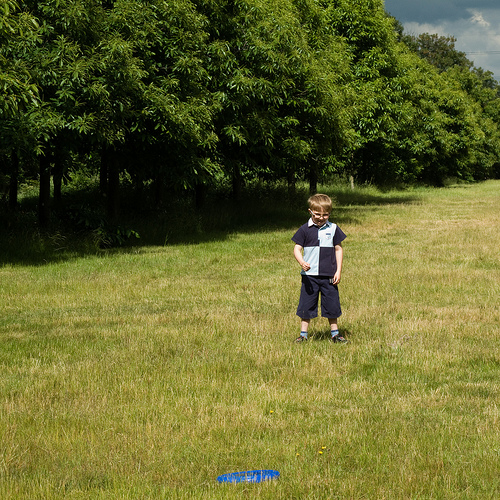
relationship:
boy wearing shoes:
[289, 186, 349, 343] [291, 323, 348, 355]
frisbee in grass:
[214, 468, 279, 484] [88, 200, 484, 470]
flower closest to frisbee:
[295, 450, 304, 462] [215, 464, 282, 476]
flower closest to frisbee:
[313, 450, 324, 456] [213, 460, 281, 487]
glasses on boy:
[308, 210, 333, 219] [289, 192, 350, 343]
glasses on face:
[308, 210, 333, 219] [312, 212, 327, 226]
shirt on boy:
[282, 217, 354, 279] [281, 187, 362, 358]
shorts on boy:
[297, 277, 340, 318] [289, 192, 350, 343]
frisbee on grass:
[214, 468, 279, 484] [5, 177, 495, 494]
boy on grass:
[289, 192, 350, 343] [41, 187, 497, 481]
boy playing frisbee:
[289, 192, 350, 343] [219, 469, 278, 483]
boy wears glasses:
[289, 192, 350, 343] [310, 201, 337, 221]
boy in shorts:
[289, 186, 349, 343] [295, 265, 344, 317]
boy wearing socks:
[289, 192, 350, 343] [296, 327, 346, 341]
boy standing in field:
[289, 192, 350, 343] [0, 171, 497, 497]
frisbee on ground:
[214, 464, 280, 499] [9, 191, 499, 498]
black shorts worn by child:
[302, 267, 345, 330] [292, 196, 348, 342]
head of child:
[303, 186, 336, 232] [276, 187, 358, 349]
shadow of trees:
[3, 183, 421, 267] [3, 0, 498, 216]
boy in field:
[289, 192, 350, 343] [1, 1, 499, 498]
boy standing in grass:
[289, 192, 350, 343] [5, 177, 495, 494]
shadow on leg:
[307, 327, 352, 342] [319, 277, 346, 343]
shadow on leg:
[307, 327, 352, 342] [293, 275, 318, 343]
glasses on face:
[309, 210, 332, 219] [311, 209, 331, 225]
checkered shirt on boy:
[288, 215, 348, 275] [289, 186, 349, 343]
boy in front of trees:
[289, 192, 350, 343] [3, 0, 498, 216]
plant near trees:
[93, 220, 140, 254] [1, 0, 499, 247]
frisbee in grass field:
[214, 468, 279, 484] [0, 171, 497, 497]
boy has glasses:
[289, 192, 350, 343] [310, 211, 329, 218]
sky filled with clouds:
[403, 1, 498, 46] [464, 40, 484, 54]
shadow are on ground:
[3, 183, 421, 267] [91, 268, 178, 327]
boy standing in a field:
[289, 192, 350, 343] [0, 171, 497, 497]